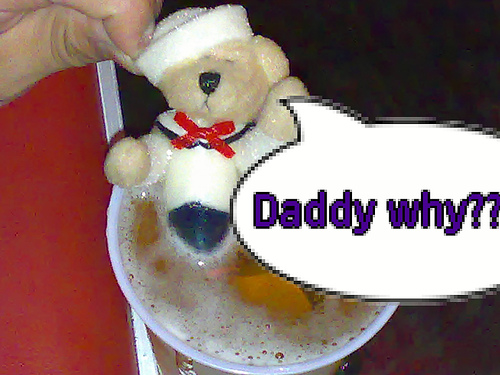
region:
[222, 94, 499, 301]
White quotation with black outline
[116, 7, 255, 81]
Cap of the teddy bear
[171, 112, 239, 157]
Red ribbon of the teddy bear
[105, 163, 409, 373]
beverege drink in a cup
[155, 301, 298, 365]
White bubble of the drink in a cup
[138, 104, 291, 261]
Sailor uniform of the teddy bear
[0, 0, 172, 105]
Fingers of a person holding a teddy bear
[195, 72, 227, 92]
Black nose of the teddy bear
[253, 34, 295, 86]
Brown left ear of the teddy bear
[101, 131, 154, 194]
left hand of the teddy bear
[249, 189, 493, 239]
letters on the picture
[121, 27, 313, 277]
a white teddy bear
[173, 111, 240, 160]
a red bow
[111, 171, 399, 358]
a cup full of a drink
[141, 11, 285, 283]
a teddy bear wearing a white hat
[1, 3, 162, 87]
the hand of the person holding the bear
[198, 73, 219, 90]
the nose of the bear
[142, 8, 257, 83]
the hat on the bear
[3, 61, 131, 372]
red on the side of the picture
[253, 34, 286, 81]
the ear of the bear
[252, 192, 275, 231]
blue letter in white bubble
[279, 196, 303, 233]
blue letter in white bubble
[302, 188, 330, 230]
blue letter in white bubble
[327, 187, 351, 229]
blue letter in white bubble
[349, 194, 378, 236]
blue letter in white bubble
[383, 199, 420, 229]
blue letter in white bubble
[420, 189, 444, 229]
blue letter in white bubble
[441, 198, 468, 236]
blue letter in white bubble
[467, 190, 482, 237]
blue question mark in white bubble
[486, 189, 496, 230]
blue question mark in white bubble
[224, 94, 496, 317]
white text bubble with blue text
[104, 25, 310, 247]
stuffed toy bear with sailor outfit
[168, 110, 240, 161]
red bow adorning sailor outfit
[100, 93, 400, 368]
clear plastic cup with beer inside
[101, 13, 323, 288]
tiny teddy bear in cup of beer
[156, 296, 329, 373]
white foamy bubbles at top of cup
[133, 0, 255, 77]
tiny white sailor hat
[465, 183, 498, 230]
two blue question marks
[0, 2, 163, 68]
thumb and finger pinching teddy bear hat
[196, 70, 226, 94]
black nose on teddy bear